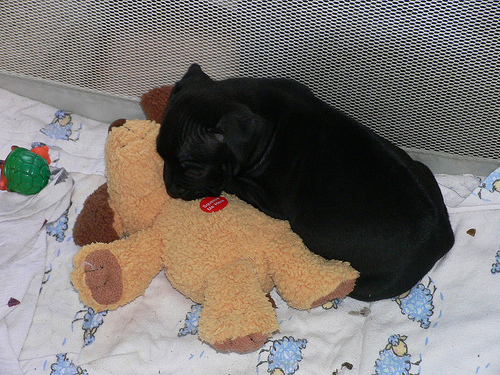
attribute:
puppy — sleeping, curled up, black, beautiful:
[157, 64, 454, 300]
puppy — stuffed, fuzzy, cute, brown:
[72, 85, 360, 353]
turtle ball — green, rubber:
[0, 145, 50, 194]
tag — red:
[199, 196, 228, 211]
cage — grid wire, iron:
[1, 0, 499, 179]